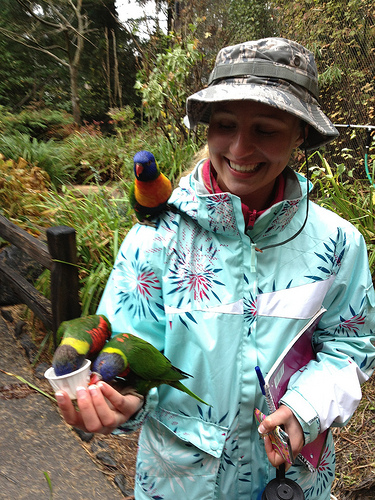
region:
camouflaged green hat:
[173, 32, 339, 152]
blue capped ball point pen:
[251, 362, 270, 414]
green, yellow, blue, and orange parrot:
[123, 148, 171, 224]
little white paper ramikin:
[38, 353, 93, 399]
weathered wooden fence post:
[38, 222, 87, 333]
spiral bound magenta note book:
[260, 305, 330, 475]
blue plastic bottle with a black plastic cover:
[253, 462, 307, 498]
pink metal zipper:
[245, 208, 259, 228]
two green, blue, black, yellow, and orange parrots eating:
[39, 312, 217, 411]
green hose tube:
[360, 141, 374, 186]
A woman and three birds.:
[28, 14, 371, 438]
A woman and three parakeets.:
[27, 27, 365, 475]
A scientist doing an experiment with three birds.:
[25, 21, 366, 484]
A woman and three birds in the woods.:
[23, 38, 366, 461]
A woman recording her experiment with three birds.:
[24, 31, 366, 497]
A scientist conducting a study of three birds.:
[29, 26, 347, 493]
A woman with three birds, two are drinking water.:
[23, 18, 355, 438]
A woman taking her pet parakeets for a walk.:
[60, 42, 361, 441]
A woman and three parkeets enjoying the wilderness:
[49, 26, 366, 470]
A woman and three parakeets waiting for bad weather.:
[50, 24, 361, 480]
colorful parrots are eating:
[43, 306, 175, 423]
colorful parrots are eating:
[71, 317, 223, 459]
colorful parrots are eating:
[20, 277, 287, 480]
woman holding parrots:
[55, 37, 374, 495]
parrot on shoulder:
[126, 150, 169, 222]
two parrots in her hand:
[48, 313, 211, 416]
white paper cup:
[43, 358, 90, 402]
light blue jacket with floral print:
[88, 161, 373, 499]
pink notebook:
[264, 305, 337, 470]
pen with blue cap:
[255, 365, 268, 396]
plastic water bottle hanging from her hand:
[253, 460, 305, 495]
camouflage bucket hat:
[177, 33, 335, 150]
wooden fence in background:
[1, 213, 76, 351]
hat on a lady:
[204, 42, 344, 113]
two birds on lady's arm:
[42, 331, 161, 399]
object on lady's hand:
[232, 362, 315, 463]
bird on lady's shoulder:
[106, 139, 190, 211]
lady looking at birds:
[207, 54, 312, 164]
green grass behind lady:
[37, 125, 117, 204]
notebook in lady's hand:
[242, 293, 345, 430]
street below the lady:
[13, 425, 74, 468]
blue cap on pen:
[244, 354, 265, 385]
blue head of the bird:
[128, 142, 173, 178]